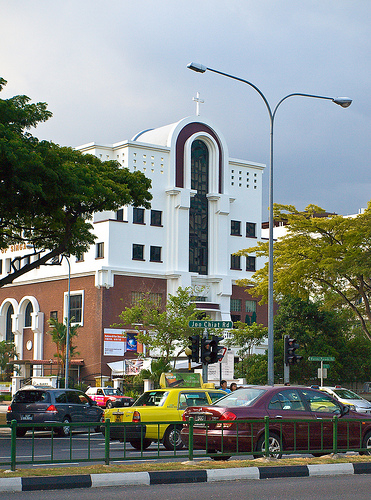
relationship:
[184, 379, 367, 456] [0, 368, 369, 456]
car on street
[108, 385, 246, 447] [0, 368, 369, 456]
car on street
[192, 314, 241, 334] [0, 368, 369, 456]
sign on street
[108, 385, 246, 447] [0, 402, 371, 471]
car on street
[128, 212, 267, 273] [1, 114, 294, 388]
windows on building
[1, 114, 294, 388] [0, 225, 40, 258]
building has writing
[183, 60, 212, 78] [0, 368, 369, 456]
lamps by street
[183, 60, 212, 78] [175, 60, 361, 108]
lamps has lamps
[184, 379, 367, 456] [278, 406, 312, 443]
car has door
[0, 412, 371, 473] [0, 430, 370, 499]
fence on ground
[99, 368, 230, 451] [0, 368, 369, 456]
car on street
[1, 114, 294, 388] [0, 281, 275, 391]
building has bricks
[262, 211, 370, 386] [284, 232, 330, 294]
tree has leaves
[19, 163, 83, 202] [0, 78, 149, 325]
leaves on tree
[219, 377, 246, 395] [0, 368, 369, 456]
people in street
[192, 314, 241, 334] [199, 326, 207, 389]
sign on pole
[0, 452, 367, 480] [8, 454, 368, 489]
grass by curb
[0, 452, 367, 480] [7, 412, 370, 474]
grass by fence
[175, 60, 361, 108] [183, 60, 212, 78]
lamps on lamps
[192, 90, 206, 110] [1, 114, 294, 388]
cross on building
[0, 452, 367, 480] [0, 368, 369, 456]
grass by street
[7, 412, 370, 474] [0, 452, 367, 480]
fence by grass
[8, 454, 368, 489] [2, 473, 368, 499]
curb near asphalt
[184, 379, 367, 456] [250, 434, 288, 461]
car has wheel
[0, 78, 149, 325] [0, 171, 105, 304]
tree has branches